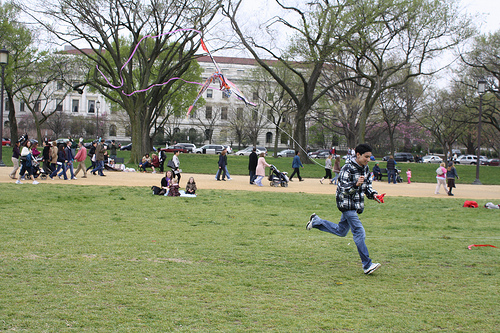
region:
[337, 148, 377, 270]
boy in flannel run with kite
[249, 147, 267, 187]
woman and man walk together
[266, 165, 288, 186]
woman is pushing stroller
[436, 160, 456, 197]
two females walking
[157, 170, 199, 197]
family sits together on grass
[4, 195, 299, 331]
green grass on ground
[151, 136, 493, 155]
cars line the parking lot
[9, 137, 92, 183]
crowd of people group together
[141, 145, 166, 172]
people together near tree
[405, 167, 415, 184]
small child in pink clothes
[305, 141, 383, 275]
young boy running in tennis shoes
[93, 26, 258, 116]
red white and blue kite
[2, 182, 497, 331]
large cut green grass park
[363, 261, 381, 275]
white and black tennis shoe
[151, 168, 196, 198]
Family having a picnic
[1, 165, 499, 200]
dirt path in a park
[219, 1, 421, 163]
large mostly bare tree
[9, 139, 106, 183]
People walking on a dirt path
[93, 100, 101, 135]
tall black lamp post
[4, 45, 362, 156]
large building with many windows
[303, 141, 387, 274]
A kid running in grass.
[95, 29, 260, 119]
A kite being pulled.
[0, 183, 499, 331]
A large area of grass.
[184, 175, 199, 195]
A child sitting down.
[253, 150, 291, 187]
A woman pushing a stroller.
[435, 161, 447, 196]
A person wearing pink.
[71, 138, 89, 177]
Someone in a red jacket.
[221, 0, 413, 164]
A large budding tree.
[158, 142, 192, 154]
A parked red car.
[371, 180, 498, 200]
A wide dirt path.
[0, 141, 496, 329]
brown path through a grassy area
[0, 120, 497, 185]
people walking to the right on brown path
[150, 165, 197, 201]
a small group sitting on the grass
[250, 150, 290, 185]
a woman pushing a stroller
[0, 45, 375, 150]
a large white building in the distance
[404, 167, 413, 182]
small child dressed all in pink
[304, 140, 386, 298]
young man running on grass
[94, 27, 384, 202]
young man is pulling a kite along with him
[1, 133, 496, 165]
cars parked beyond grass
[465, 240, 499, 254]
red, ribbon-like object on the ground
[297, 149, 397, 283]
man running on a field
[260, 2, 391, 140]
trees on grass in back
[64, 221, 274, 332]
large grass field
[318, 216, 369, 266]
jeans on legs of man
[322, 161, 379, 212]
flannel top on man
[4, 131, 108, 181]
people walking on dirt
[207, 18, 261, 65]
small kite in the air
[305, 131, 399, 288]
man flying a kite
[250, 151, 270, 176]
woman pushing a stroller